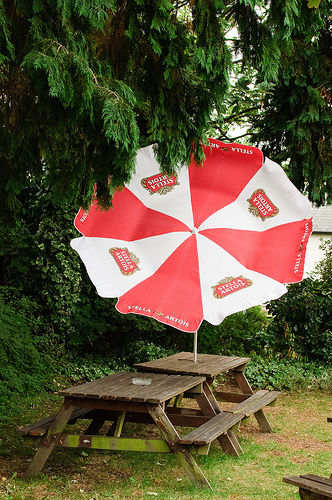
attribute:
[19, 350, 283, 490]
tables — weathered, brown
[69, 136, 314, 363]
umbrella — red, white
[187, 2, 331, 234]
roof — gray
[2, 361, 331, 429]
weeds — green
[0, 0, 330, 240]
tree — large, green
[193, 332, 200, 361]
post — silver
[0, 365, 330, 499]
land — grassy, green, brown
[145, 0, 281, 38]
sky — gray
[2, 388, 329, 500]
grass — short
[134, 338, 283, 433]
table — brown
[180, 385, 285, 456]
seats — wooden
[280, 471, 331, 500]
bench — brown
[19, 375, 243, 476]
table — brown